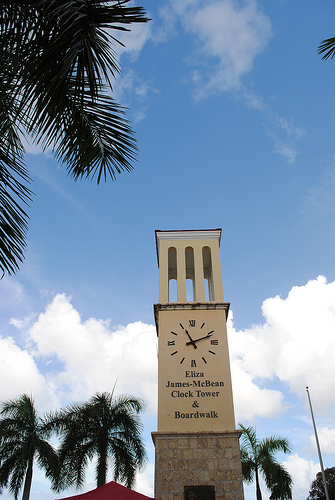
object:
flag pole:
[305, 385, 329, 497]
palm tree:
[0, 394, 73, 497]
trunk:
[20, 453, 35, 498]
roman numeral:
[209, 339, 219, 343]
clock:
[167, 319, 219, 368]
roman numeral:
[208, 350, 215, 355]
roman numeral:
[202, 356, 207, 364]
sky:
[0, 2, 333, 497]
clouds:
[238, 275, 332, 421]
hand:
[186, 334, 214, 347]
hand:
[185, 329, 198, 349]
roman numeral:
[191, 359, 197, 367]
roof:
[54, 480, 156, 499]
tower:
[149, 228, 244, 500]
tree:
[44, 391, 147, 490]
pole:
[303, 384, 329, 500]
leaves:
[81, 410, 98, 427]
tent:
[54, 482, 152, 500]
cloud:
[24, 291, 158, 414]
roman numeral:
[188, 319, 195, 327]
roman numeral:
[210, 340, 218, 346]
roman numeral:
[167, 340, 175, 346]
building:
[150, 228, 245, 498]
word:
[175, 411, 219, 419]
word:
[171, 390, 193, 397]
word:
[195, 390, 221, 397]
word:
[165, 380, 224, 388]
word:
[185, 371, 204, 377]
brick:
[157, 437, 167, 448]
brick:
[176, 437, 188, 444]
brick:
[184, 447, 202, 459]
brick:
[223, 445, 233, 459]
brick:
[154, 480, 174, 492]